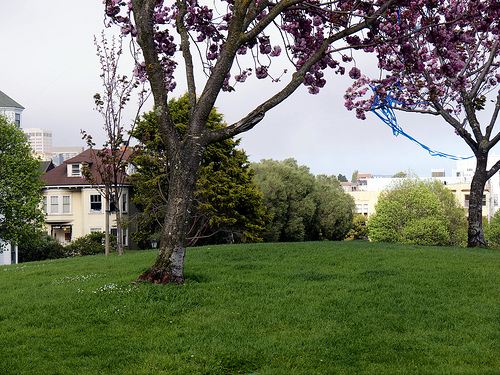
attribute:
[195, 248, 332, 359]
grass — green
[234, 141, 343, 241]
trees — green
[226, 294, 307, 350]
lawn — green and grassy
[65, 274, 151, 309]
flowers — white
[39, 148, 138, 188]
roof — brown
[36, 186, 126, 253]
house — cream colored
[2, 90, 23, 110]
roof — gray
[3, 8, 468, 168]
sky — gray, overhead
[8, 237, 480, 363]
ground — green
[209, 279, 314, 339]
grass — green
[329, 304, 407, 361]
grass — green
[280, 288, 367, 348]
grass — green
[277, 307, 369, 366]
grass — green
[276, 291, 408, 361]
grass — green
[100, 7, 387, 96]
blossoms — purple